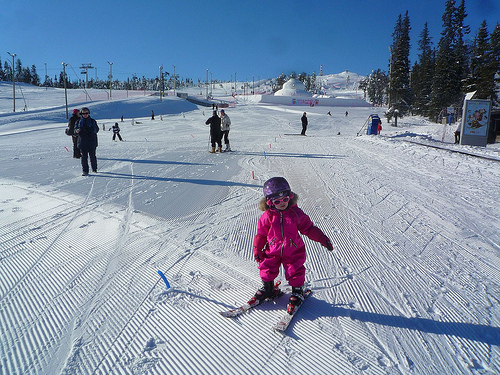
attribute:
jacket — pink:
[257, 213, 308, 256]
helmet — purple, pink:
[263, 175, 290, 195]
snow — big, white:
[28, 112, 473, 374]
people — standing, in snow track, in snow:
[206, 111, 243, 155]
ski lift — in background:
[22, 56, 246, 98]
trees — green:
[365, 22, 484, 106]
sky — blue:
[10, 3, 393, 68]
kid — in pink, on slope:
[243, 176, 340, 295]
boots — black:
[259, 283, 306, 309]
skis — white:
[234, 287, 316, 332]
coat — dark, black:
[77, 119, 97, 143]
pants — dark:
[79, 148, 99, 167]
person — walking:
[75, 106, 107, 173]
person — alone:
[295, 111, 310, 141]